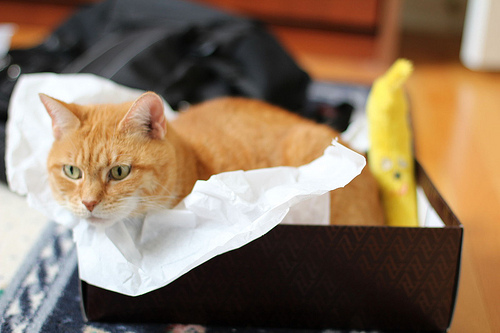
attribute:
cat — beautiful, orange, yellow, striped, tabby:
[40, 90, 390, 226]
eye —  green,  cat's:
[103, 162, 132, 180]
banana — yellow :
[348, 53, 428, 233]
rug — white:
[3, 213, 192, 331]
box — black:
[81, 145, 466, 324]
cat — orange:
[36, 81, 382, 233]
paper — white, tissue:
[2, 70, 368, 300]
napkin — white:
[176, 137, 368, 238]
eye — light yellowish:
[56, 159, 84, 184]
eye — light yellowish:
[103, 160, 132, 182]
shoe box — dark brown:
[69, 165, 461, 331]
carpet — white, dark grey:
[1, 180, 88, 328]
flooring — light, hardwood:
[415, 60, 498, 203]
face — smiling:
[371, 153, 416, 198]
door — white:
[451, 3, 496, 73]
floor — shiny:
[445, 79, 479, 179]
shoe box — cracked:
[410, 214, 473, 279]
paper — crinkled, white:
[89, 173, 315, 290]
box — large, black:
[76, 178, 467, 331]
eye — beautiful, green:
[103, 159, 134, 180]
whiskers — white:
[136, 104, 153, 128]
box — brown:
[73, 160, 466, 328]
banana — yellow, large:
[365, 56, 420, 227]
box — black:
[100, 194, 460, 305]